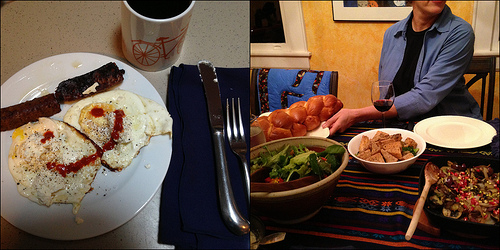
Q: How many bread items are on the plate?
A: One.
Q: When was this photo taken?
A: At dinner time.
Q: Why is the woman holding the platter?
A: She is passing the food.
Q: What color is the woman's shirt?
A: It is a blue jean shirt.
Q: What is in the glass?
A: Red wine.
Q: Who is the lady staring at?
A: The person next to her.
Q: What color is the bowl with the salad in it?
A: Brown.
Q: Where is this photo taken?
A: The dining room.